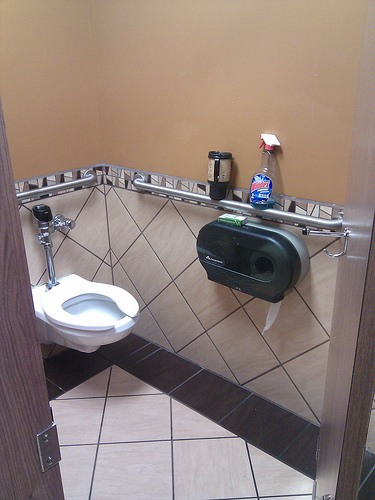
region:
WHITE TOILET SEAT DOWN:
[40, 276, 141, 332]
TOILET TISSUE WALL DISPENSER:
[199, 211, 302, 301]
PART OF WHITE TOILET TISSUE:
[261, 305, 290, 339]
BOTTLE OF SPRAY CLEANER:
[247, 128, 281, 209]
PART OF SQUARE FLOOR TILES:
[82, 445, 151, 497]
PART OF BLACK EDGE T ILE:
[216, 389, 277, 440]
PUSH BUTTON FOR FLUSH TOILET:
[34, 204, 60, 224]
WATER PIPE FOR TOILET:
[39, 227, 60, 282]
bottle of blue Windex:
[245, 130, 279, 208]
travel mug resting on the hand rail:
[200, 146, 234, 201]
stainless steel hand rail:
[18, 168, 103, 203]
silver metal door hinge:
[34, 419, 66, 475]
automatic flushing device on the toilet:
[29, 198, 56, 222]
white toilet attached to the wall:
[36, 275, 144, 356]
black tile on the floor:
[165, 361, 255, 427]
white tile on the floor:
[94, 388, 174, 444]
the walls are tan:
[1, 1, 347, 206]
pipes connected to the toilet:
[37, 213, 82, 284]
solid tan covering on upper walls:
[0, 0, 360, 204]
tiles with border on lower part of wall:
[15, 158, 346, 428]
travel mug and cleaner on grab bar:
[128, 127, 342, 228]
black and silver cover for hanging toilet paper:
[185, 202, 305, 332]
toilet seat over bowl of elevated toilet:
[30, 270, 142, 375]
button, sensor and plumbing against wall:
[30, 202, 75, 286]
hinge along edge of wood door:
[0, 204, 60, 492]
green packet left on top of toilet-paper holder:
[210, 206, 255, 243]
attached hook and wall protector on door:
[296, 222, 356, 258]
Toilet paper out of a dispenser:
[261, 303, 282, 334]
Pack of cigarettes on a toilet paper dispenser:
[218, 212, 248, 225]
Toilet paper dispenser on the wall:
[193, 217, 305, 301]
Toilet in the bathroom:
[27, 273, 141, 353]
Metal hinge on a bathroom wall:
[32, 406, 62, 474]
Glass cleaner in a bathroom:
[250, 130, 283, 208]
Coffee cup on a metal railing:
[204, 148, 232, 200]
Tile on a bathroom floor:
[19, 332, 373, 499]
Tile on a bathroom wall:
[99, 164, 371, 449]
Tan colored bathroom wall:
[1, 0, 346, 207]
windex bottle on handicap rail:
[247, 128, 286, 216]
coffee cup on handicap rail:
[195, 142, 237, 205]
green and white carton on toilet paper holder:
[203, 209, 254, 231]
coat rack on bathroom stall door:
[296, 215, 356, 269]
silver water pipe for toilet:
[31, 201, 85, 275]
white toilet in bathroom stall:
[30, 266, 147, 363]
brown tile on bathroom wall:
[178, 301, 256, 355]